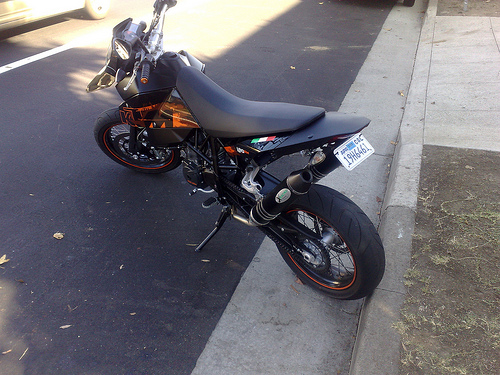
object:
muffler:
[245, 166, 315, 230]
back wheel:
[269, 183, 388, 300]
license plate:
[333, 130, 377, 172]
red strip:
[122, 102, 176, 125]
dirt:
[397, 143, 500, 374]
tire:
[270, 184, 386, 302]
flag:
[249, 134, 277, 146]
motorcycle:
[85, 0, 389, 300]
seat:
[174, 66, 327, 137]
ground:
[424, 16, 499, 150]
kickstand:
[194, 182, 235, 253]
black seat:
[175, 67, 327, 139]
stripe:
[285, 183, 386, 301]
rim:
[279, 208, 358, 291]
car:
[0, 0, 111, 36]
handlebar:
[140, 56, 152, 84]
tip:
[140, 76, 149, 84]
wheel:
[93, 107, 189, 176]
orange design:
[117, 104, 204, 129]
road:
[0, 0, 431, 374]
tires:
[92, 108, 387, 302]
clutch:
[114, 53, 142, 106]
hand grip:
[123, 50, 154, 90]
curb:
[296, 306, 405, 375]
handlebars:
[86, 0, 174, 95]